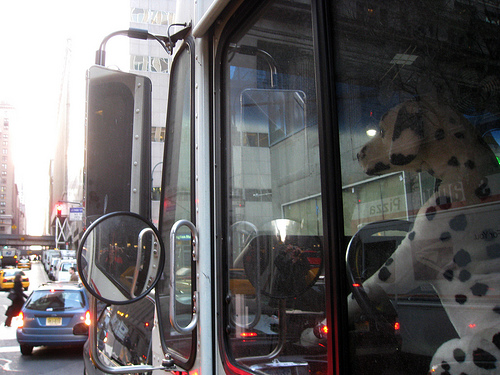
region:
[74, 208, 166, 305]
A side mirror of a vehicle.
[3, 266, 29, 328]
A person crossing the street.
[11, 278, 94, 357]
A light blue vehicle.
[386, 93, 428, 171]
A ear on a dog.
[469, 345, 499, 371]
A spot on a dalmatian.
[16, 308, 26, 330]
The tail light on a car.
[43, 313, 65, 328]
A license plate on a car.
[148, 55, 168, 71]
A window on a building.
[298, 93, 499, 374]
A dog inside a vehicle.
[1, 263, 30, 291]
A yellow vehicle on the street.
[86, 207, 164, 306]
rear view mirrow on firetruck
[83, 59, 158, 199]
rear view mirrow on firetruck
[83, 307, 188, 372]
rear view mirrow on firetruck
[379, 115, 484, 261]
dalmation in fire truck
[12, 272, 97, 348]
blue station wagon on road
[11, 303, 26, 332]
illuminated brake light on car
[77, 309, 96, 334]
illuminated brake light on car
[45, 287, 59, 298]
illuminated brake light on car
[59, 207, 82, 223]
red street light over road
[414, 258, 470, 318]
black spots on dog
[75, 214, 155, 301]
the round silver mirror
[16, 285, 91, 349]
a light blue silver car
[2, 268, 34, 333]
a person walking across the street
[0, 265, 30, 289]
a bright yellow taxi on the street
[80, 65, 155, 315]
a long mirror on the vehicle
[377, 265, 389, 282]
the black spot on a dog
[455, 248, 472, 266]
the black spot on a dog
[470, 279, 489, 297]
the black spot on a dog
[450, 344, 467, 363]
the black spot on a dog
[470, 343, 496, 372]
the black spot on a dog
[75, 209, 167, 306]
a side mirror of the bus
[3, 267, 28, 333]
a woman cross the street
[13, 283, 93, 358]
a blue car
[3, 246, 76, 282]
traffic jam ahead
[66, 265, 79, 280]
a man walking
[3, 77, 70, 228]
buildings in the background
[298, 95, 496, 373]
a stuff toy dog in the bus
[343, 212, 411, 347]
a steering wheel of the bus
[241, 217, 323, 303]
a reflection of the side mirror on the glass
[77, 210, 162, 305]
a reflection of the side of bus in the side mirror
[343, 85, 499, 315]
dalmation dog at steering wheel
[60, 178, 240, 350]
rear view mirror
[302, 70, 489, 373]
dog driving a truck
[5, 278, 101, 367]
rear view of blue car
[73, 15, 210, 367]
rear view mirrors on fire truck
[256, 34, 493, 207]
dalmation dog looking out window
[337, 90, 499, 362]
dalmation driving fire truck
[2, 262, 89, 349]
person crossing street in front of blue car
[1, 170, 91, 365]
city street with cars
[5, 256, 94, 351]
pedestrian crossing street